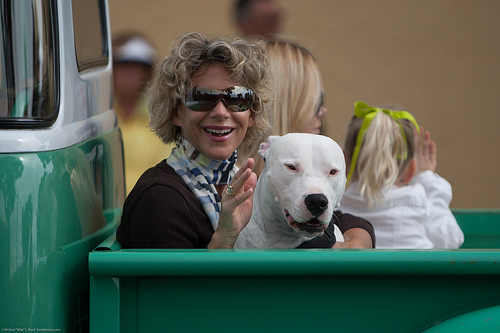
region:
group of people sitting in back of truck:
[134, 37, 496, 279]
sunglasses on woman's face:
[181, 85, 253, 109]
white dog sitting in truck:
[239, 129, 345, 244]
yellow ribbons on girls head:
[345, 97, 424, 164]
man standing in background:
[93, 7, 165, 127]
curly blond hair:
[141, 30, 273, 154]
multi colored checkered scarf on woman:
[163, 140, 248, 216]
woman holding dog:
[123, 47, 388, 254]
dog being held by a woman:
[129, 34, 387, 290]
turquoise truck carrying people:
[6, 7, 486, 332]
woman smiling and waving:
[116, 30, 272, 245]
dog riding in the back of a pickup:
[230, 132, 348, 249]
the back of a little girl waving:
[340, 98, 466, 248]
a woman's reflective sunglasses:
[180, 84, 258, 112]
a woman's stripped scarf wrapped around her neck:
[164, 135, 241, 233]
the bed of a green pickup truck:
[87, 247, 498, 329]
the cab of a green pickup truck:
[0, 0, 132, 330]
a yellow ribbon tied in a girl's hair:
[345, 100, 422, 185]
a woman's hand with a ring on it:
[205, 155, 261, 247]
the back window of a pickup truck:
[70, 0, 107, 74]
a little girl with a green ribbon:
[346, 103, 423, 180]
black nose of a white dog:
[300, 191, 337, 216]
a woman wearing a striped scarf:
[174, 134, 246, 228]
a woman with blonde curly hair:
[156, 38, 283, 159]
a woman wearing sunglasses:
[180, 77, 257, 118]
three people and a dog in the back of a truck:
[117, 32, 462, 277]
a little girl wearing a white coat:
[339, 99, 447, 256]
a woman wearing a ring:
[221, 177, 239, 197]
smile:
[192, 121, 243, 143]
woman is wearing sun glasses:
[164, 67, 261, 117]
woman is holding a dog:
[118, 37, 405, 322]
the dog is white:
[242, 130, 384, 282]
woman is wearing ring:
[216, 173, 241, 201]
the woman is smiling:
[132, 24, 299, 185]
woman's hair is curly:
[138, 28, 286, 180]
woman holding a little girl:
[266, 25, 454, 218]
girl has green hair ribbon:
[331, 77, 441, 196]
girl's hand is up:
[410, 123, 445, 182]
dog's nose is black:
[295, 178, 345, 225]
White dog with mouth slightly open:
[231, 123, 354, 249]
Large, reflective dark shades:
[178, 84, 257, 114]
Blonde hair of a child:
[339, 101, 454, 251]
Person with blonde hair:
[235, 33, 330, 135]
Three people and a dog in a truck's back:
[5, 20, 495, 325]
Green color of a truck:
[0, 155, 495, 328]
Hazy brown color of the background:
[316, 2, 494, 109]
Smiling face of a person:
[143, 29, 274, 164]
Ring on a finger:
[223, 182, 238, 199]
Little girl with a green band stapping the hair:
[340, 92, 426, 202]